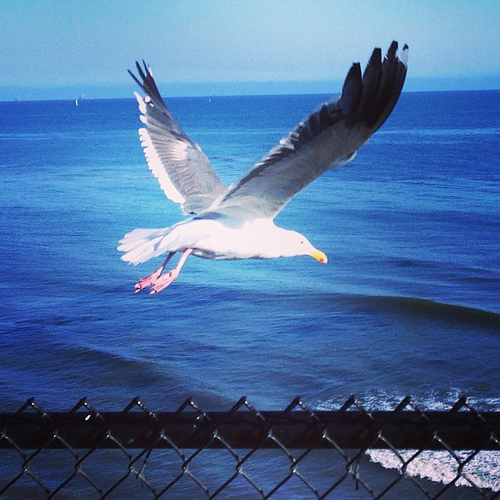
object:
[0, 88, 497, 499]
water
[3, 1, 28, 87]
sky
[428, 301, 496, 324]
wave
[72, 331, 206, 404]
wave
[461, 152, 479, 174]
ground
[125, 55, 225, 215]
wing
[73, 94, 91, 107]
boat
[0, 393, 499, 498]
fence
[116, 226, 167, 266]
feathers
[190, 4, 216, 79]
sky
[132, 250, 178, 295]
leg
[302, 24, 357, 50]
sky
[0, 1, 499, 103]
sky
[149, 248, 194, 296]
legs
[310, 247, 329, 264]
beak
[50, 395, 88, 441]
wire mess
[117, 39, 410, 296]
bird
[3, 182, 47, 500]
water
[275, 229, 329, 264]
head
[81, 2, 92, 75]
sky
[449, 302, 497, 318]
wave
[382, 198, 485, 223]
wave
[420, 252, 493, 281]
wave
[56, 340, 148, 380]
wave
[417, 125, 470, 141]
wave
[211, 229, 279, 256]
feathers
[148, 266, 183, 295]
feet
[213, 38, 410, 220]
feathers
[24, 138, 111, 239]
sea water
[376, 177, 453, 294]
sea water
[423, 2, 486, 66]
sky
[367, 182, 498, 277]
water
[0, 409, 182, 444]
rod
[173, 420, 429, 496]
fencing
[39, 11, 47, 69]
sky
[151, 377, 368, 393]
water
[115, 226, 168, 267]
tail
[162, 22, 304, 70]
clouds